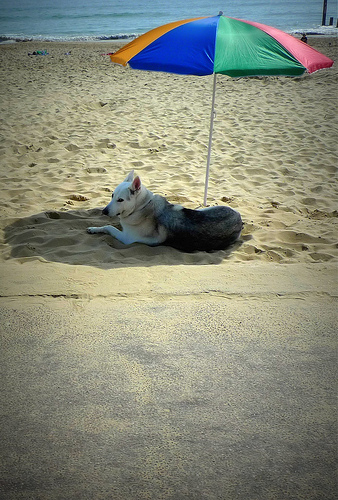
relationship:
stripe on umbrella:
[216, 12, 303, 80] [107, 9, 337, 162]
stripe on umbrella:
[110, 16, 196, 68] [136, 19, 320, 80]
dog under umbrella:
[87, 167, 244, 254] [108, 11, 336, 207]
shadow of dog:
[0, 203, 248, 272] [87, 167, 244, 254]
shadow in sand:
[0, 203, 248, 272] [0, 34, 337, 498]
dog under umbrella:
[87, 167, 244, 254] [111, 11, 335, 85]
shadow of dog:
[5, 188, 252, 284] [87, 167, 244, 254]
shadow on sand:
[5, 188, 252, 284] [3, 39, 336, 260]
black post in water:
[320, 0, 329, 24] [2, 0, 336, 47]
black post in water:
[328, 16, 330, 22] [2, 0, 336, 47]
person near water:
[300, 32, 307, 44] [1, 0, 330, 35]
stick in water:
[325, 16, 333, 18] [2, 1, 337, 38]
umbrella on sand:
[108, 11, 336, 207] [3, 39, 336, 260]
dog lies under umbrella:
[87, 167, 244, 254] [107, 11, 332, 233]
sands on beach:
[2, 39, 336, 262] [4, 41, 333, 262]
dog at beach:
[86, 170, 244, 254] [0, 36, 337, 498]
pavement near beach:
[0, 297, 337, 498] [0, 39, 335, 297]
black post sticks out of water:
[321, 0, 328, 27] [1, 0, 330, 35]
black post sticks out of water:
[329, 16, 334, 24] [1, 0, 330, 35]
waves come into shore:
[48, 4, 308, 57] [0, 28, 337, 38]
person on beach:
[299, 33, 308, 44] [4, 41, 333, 262]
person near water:
[299, 33, 308, 44] [1, 0, 330, 35]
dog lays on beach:
[87, 167, 244, 254] [0, 36, 337, 498]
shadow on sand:
[0, 203, 248, 272] [18, 81, 130, 182]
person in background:
[300, 32, 307, 44] [1, 1, 336, 104]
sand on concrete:
[23, 271, 168, 323] [10, 297, 336, 496]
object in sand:
[27, 49, 50, 55] [3, 39, 336, 260]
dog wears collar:
[87, 167, 244, 254] [140, 196, 153, 209]